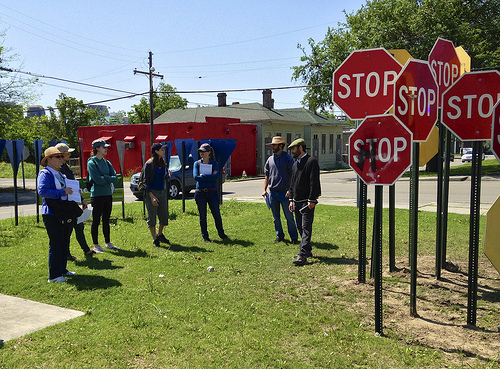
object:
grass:
[208, 272, 272, 309]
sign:
[329, 46, 401, 121]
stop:
[338, 67, 400, 103]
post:
[370, 182, 390, 337]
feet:
[217, 233, 235, 244]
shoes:
[199, 235, 214, 245]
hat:
[288, 135, 309, 151]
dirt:
[413, 324, 499, 368]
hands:
[303, 200, 317, 211]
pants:
[292, 197, 317, 255]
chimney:
[260, 85, 277, 109]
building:
[258, 86, 342, 173]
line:
[73, 86, 329, 106]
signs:
[441, 69, 500, 143]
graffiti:
[356, 138, 380, 173]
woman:
[192, 138, 235, 243]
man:
[287, 135, 325, 266]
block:
[1, 288, 88, 343]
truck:
[131, 150, 227, 202]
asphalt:
[322, 174, 353, 203]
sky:
[4, 0, 286, 53]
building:
[75, 113, 263, 184]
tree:
[131, 82, 189, 123]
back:
[1, 85, 499, 178]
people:
[136, 137, 176, 249]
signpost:
[395, 58, 439, 320]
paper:
[197, 160, 214, 180]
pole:
[133, 50, 167, 141]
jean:
[266, 190, 299, 239]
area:
[118, 310, 214, 368]